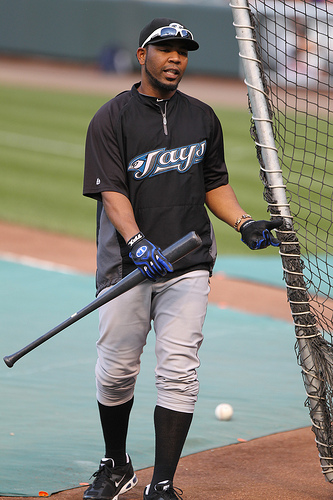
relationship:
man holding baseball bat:
[65, 11, 283, 499] [2, 230, 202, 367]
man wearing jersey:
[65, 11, 283, 499] [131, 118, 234, 227]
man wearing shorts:
[65, 11, 283, 499] [94, 268, 210, 414]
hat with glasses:
[137, 16, 198, 51] [138, 24, 194, 40]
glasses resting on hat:
[140, 22, 193, 48] [135, 17, 200, 52]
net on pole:
[227, 0, 333, 487] [226, 4, 332, 373]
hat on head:
[139, 22, 200, 52] [140, 41, 194, 89]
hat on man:
[139, 22, 200, 52] [65, 11, 283, 499]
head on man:
[140, 41, 194, 89] [65, 11, 283, 499]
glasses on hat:
[140, 22, 193, 48] [128, 3, 221, 68]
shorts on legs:
[91, 263, 210, 419] [123, 282, 229, 468]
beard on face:
[141, 67, 183, 92] [135, 36, 188, 88]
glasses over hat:
[140, 22, 193, 48] [132, 12, 203, 51]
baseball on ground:
[216, 403, 232, 419] [76, 360, 302, 480]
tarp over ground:
[3, 258, 309, 496] [197, 441, 314, 497]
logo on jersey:
[128, 135, 215, 184] [82, 78, 231, 296]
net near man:
[252, 13, 330, 491] [82, 18, 283, 500]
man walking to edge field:
[82, 18, 283, 500] [1, 63, 332, 498]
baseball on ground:
[215, 403, 234, 422] [0, 52, 333, 497]